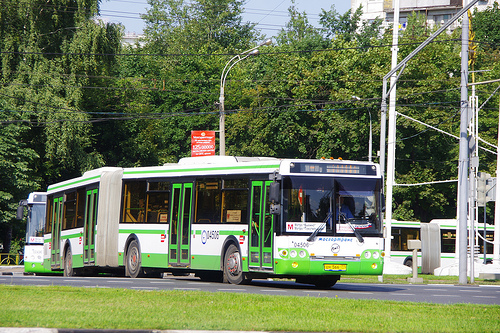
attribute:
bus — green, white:
[44, 155, 385, 285]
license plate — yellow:
[323, 264, 346, 272]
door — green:
[168, 182, 182, 266]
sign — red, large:
[190, 131, 215, 157]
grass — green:
[1, 284, 498, 332]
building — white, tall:
[350, 1, 499, 38]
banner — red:
[191, 130, 216, 157]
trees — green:
[1, 1, 498, 253]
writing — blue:
[317, 237, 353, 243]